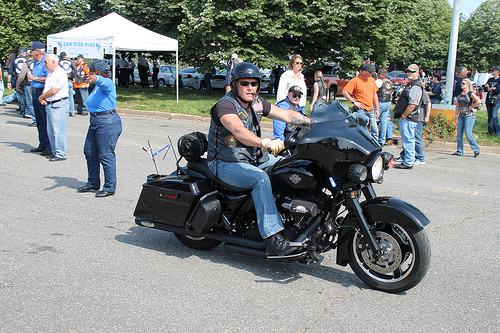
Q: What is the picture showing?
A: It is showing a pavement.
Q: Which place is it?
A: It is a pavement.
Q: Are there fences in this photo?
A: No, there are no fences.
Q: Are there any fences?
A: No, there are no fences.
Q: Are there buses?
A: No, there are no buses.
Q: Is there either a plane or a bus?
A: No, there are no buses or airplanes.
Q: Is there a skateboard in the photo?
A: No, there are no skateboards.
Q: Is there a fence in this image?
A: No, there are no fences.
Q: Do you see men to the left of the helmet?
A: No, the man is to the right of the helmet.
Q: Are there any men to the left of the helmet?
A: No, the man is to the right of the helmet.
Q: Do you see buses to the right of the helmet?
A: No, there is a man to the right of the helmet.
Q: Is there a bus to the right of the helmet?
A: No, there is a man to the right of the helmet.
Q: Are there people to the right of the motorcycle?
A: No, the person is to the left of the motorcycle.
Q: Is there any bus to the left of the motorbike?
A: No, there is a person to the left of the motorbike.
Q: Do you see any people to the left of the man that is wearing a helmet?
A: Yes, there is a person to the left of the man.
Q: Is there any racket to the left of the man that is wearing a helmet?
A: No, there is a person to the left of the man.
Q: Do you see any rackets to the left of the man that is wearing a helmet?
A: No, there is a person to the left of the man.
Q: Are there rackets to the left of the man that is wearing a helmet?
A: No, there is a person to the left of the man.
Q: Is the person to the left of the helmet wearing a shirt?
A: Yes, the person is wearing a shirt.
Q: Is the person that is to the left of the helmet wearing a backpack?
A: No, the person is wearing a shirt.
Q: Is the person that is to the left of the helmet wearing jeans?
A: Yes, the person is wearing jeans.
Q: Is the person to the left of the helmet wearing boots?
A: No, the person is wearing jeans.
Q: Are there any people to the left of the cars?
A: Yes, there is a person to the left of the cars.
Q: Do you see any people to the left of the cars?
A: Yes, there is a person to the left of the cars.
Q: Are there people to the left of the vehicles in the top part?
A: Yes, there is a person to the left of the cars.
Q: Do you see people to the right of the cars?
A: No, the person is to the left of the cars.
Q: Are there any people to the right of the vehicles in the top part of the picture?
A: No, the person is to the left of the cars.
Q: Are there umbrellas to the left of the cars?
A: No, there is a person to the left of the cars.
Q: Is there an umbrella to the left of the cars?
A: No, there is a person to the left of the cars.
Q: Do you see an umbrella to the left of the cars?
A: No, there is a person to the left of the cars.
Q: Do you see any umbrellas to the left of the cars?
A: No, there is a person to the left of the cars.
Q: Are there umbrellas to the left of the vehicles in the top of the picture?
A: No, there is a person to the left of the cars.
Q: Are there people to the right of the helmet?
A: No, the person is to the left of the helmet.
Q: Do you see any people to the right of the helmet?
A: No, the person is to the left of the helmet.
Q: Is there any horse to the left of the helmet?
A: No, there is a person to the left of the helmet.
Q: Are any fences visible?
A: No, there are no fences.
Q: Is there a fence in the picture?
A: No, there are no fences.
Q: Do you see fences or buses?
A: No, there are no fences or buses.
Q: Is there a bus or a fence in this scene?
A: No, there are no fences or buses.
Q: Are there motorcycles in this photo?
A: Yes, there is a motorcycle.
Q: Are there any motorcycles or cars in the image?
A: Yes, there is a motorcycle.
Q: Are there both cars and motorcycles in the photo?
A: Yes, there are both a motorcycle and a car.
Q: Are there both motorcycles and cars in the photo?
A: Yes, there are both a motorcycle and a car.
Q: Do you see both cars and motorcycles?
A: Yes, there are both a motorcycle and a car.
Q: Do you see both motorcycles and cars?
A: Yes, there are both a motorcycle and a car.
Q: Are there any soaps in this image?
A: No, there are no soaps.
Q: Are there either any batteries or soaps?
A: No, there are no soaps or batteries.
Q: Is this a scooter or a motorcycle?
A: This is a motorcycle.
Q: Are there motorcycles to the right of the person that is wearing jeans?
A: Yes, there is a motorcycle to the right of the person.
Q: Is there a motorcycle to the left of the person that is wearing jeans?
A: No, the motorcycle is to the right of the person.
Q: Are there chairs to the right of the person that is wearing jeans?
A: No, there is a motorcycle to the right of the person.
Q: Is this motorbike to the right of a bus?
A: No, the motorbike is to the right of a person.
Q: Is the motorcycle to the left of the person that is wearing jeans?
A: No, the motorcycle is to the right of the person.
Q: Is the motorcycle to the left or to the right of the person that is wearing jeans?
A: The motorcycle is to the right of the person.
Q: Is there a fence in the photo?
A: No, there are no fences.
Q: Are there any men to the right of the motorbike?
A: No, the man is to the left of the motorbike.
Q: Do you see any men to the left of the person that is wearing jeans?
A: Yes, there is a man to the left of the person.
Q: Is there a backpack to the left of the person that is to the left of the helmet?
A: No, there is a man to the left of the person.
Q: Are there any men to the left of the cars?
A: Yes, there is a man to the left of the cars.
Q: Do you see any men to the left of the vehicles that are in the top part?
A: Yes, there is a man to the left of the cars.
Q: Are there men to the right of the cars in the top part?
A: No, the man is to the left of the cars.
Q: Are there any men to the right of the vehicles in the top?
A: No, the man is to the left of the cars.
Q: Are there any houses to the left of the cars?
A: No, there is a man to the left of the cars.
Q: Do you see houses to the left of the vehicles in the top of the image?
A: No, there is a man to the left of the cars.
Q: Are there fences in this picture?
A: No, there are no fences.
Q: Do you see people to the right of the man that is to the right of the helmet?
A: Yes, there is a person to the right of the man.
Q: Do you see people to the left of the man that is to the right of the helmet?
A: No, the person is to the right of the man.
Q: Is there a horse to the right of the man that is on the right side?
A: No, there is a person to the right of the man.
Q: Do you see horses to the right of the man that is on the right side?
A: No, there is a person to the right of the man.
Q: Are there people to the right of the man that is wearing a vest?
A: Yes, there is a person to the right of the man.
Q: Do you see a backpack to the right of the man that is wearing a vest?
A: No, there is a person to the right of the man.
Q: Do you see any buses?
A: No, there are no buses.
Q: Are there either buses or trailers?
A: No, there are no buses or trailers.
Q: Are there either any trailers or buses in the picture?
A: No, there are no buses or trailers.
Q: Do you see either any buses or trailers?
A: No, there are no buses or trailers.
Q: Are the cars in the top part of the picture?
A: Yes, the cars are in the top of the image.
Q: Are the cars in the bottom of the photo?
A: No, the cars are in the top of the image.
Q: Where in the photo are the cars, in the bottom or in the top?
A: The cars are in the top of the image.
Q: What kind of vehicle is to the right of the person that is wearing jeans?
A: The vehicles are cars.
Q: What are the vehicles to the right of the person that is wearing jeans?
A: The vehicles are cars.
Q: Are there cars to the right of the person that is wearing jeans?
A: Yes, there are cars to the right of the person.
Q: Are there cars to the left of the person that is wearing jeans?
A: No, the cars are to the right of the person.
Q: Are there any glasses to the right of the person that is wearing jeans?
A: No, there are cars to the right of the person.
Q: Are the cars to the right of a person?
A: Yes, the cars are to the right of a person.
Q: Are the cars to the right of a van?
A: No, the cars are to the right of a person.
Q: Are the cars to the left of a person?
A: No, the cars are to the right of a person.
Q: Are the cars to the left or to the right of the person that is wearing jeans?
A: The cars are to the right of the person.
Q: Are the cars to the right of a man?
A: Yes, the cars are to the right of a man.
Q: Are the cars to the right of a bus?
A: No, the cars are to the right of a man.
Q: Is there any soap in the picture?
A: No, there are no soaps.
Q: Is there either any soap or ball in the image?
A: No, there are no soaps or balls.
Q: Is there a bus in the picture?
A: No, there are no buses.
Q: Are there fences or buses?
A: No, there are no buses or fences.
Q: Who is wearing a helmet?
A: The man is wearing a helmet.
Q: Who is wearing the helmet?
A: The man is wearing a helmet.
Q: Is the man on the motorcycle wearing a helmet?
A: Yes, the man is wearing a helmet.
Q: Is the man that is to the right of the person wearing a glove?
A: No, the man is wearing a helmet.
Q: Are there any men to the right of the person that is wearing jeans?
A: Yes, there is a man to the right of the person.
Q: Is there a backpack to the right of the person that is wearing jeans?
A: No, there is a man to the right of the person.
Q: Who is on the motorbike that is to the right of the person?
A: The man is on the motorcycle.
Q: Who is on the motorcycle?
A: The man is on the motorcycle.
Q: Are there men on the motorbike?
A: Yes, there is a man on the motorbike.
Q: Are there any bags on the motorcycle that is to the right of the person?
A: No, there is a man on the motorcycle.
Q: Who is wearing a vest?
A: The man is wearing a vest.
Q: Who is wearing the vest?
A: The man is wearing a vest.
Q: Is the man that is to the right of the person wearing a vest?
A: Yes, the man is wearing a vest.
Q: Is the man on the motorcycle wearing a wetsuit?
A: No, the man is wearing a vest.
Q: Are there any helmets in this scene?
A: Yes, there is a helmet.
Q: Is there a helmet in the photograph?
A: Yes, there is a helmet.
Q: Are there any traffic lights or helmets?
A: Yes, there is a helmet.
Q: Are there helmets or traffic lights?
A: Yes, there is a helmet.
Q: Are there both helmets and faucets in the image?
A: No, there is a helmet but no faucets.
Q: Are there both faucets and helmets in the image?
A: No, there is a helmet but no faucets.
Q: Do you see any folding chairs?
A: No, there are no folding chairs.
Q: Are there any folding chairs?
A: No, there are no folding chairs.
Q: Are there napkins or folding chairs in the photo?
A: No, there are no folding chairs or napkins.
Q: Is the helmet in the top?
A: Yes, the helmet is in the top of the image.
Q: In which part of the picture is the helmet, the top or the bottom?
A: The helmet is in the top of the image.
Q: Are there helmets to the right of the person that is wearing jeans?
A: Yes, there is a helmet to the right of the person.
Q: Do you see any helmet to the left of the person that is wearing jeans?
A: No, the helmet is to the right of the person.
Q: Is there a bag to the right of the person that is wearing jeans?
A: No, there is a helmet to the right of the person.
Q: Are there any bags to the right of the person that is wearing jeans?
A: No, there is a helmet to the right of the person.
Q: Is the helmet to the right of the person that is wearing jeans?
A: Yes, the helmet is to the right of the person.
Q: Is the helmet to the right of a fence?
A: No, the helmet is to the right of the person.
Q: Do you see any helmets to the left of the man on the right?
A: Yes, there is a helmet to the left of the man.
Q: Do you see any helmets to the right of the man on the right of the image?
A: No, the helmet is to the left of the man.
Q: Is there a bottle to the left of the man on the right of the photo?
A: No, there is a helmet to the left of the man.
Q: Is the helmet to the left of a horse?
A: No, the helmet is to the left of the man.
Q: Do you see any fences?
A: No, there are no fences.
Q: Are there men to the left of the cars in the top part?
A: Yes, there is a man to the left of the cars.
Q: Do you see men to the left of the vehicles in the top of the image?
A: Yes, there is a man to the left of the cars.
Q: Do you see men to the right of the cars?
A: No, the man is to the left of the cars.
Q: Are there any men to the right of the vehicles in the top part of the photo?
A: No, the man is to the left of the cars.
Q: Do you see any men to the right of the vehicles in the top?
A: No, the man is to the left of the cars.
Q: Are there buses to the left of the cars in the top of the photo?
A: No, there is a man to the left of the cars.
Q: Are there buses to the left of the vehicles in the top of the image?
A: No, there is a man to the left of the cars.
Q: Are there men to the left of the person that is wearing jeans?
A: Yes, there is a man to the left of the person.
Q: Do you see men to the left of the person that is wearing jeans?
A: Yes, there is a man to the left of the person.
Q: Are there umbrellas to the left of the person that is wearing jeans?
A: No, there is a man to the left of the person.